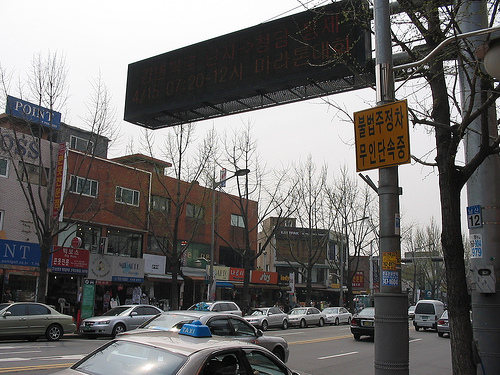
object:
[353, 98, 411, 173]
sign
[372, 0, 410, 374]
post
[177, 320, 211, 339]
taxi cab sign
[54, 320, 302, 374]
taxi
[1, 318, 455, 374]
street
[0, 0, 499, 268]
sky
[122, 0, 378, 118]
street signal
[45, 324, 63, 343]
tire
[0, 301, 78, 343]
car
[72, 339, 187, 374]
window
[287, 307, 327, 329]
cars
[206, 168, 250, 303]
street lamp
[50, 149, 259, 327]
building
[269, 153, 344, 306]
tree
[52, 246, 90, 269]
sign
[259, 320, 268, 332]
wheel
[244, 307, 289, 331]
car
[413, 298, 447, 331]
van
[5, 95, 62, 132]
sign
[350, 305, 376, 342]
car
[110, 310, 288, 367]
car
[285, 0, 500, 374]
tree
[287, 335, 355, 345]
yellow stripe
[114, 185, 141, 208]
window